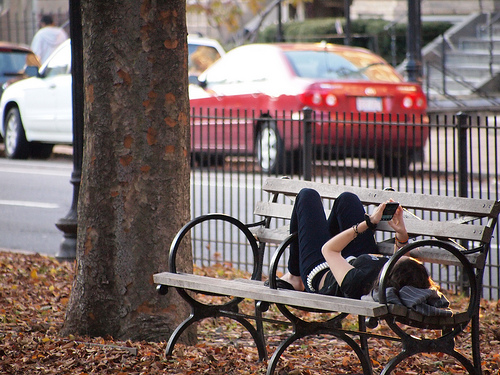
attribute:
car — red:
[193, 35, 436, 184]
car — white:
[0, 36, 82, 160]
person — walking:
[20, 9, 71, 75]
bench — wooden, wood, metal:
[145, 170, 494, 362]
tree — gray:
[61, 6, 210, 341]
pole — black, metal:
[53, 3, 87, 261]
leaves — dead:
[4, 257, 69, 373]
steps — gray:
[402, 11, 498, 110]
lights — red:
[302, 89, 343, 109]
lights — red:
[396, 88, 430, 111]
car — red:
[189, 38, 432, 173]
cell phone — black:
[380, 200, 400, 222]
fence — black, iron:
[191, 100, 498, 296]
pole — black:
[249, 300, 266, 357]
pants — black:
[286, 187, 365, 291]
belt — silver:
[303, 254, 356, 286]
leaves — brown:
[4, 250, 484, 370]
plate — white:
[354, 93, 384, 112]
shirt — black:
[323, 255, 385, 296]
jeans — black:
[285, 185, 364, 294]